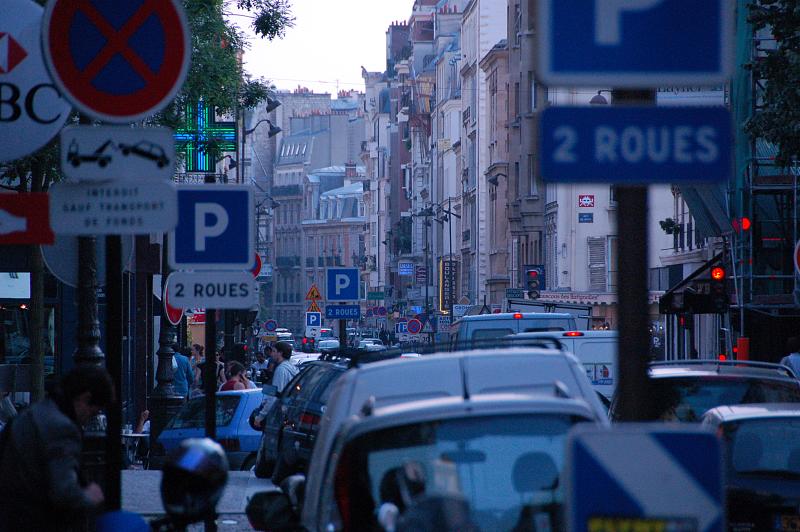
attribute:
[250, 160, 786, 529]
busy street — BUSY , CONGESTED 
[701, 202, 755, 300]
traffic light — red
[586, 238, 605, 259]
window — on a building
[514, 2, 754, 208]
blue sign — blue 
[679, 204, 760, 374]
traffic light — red 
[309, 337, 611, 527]
white van — white 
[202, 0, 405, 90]
sky — white 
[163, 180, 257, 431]
street sign — blue and white 